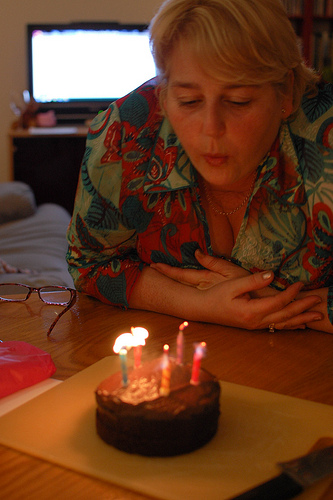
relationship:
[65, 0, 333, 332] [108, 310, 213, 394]
woman blows candles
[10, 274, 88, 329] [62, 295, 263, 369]
glasses are on tables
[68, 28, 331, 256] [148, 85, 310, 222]
woman wearing necklace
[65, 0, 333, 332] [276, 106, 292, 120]
woman wearing earring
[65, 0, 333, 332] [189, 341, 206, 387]
woman blowing out candle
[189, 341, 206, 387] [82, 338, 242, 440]
candle are on cake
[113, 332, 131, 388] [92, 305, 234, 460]
candle are on cake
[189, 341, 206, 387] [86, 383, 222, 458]
candle are on cake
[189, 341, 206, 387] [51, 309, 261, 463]
candle are on cake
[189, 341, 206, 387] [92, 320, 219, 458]
candle are on cake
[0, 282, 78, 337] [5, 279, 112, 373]
glasses are on table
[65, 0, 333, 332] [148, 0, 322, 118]
woman with blondehair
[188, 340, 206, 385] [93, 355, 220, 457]
candle on cake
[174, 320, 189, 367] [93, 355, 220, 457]
candle on cake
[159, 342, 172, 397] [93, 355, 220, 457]
candle on cake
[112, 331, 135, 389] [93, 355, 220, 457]
candle on cake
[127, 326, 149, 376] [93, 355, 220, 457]
candle on cake